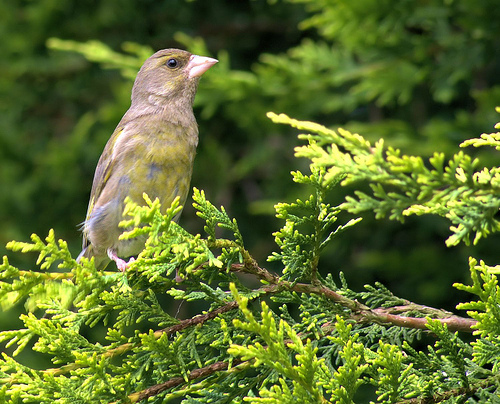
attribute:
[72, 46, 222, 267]
bird — brown, small, sideways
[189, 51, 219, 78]
beak — sharp, white, beige, pink, pointy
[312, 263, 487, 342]
branch — brown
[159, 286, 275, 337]
branch — weak, thin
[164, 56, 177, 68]
eye — round, black, beady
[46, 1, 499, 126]
leaves — green, blurry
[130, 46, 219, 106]
head — light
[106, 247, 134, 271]
foot — small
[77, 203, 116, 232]
feather — blue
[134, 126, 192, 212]
stomach — yellow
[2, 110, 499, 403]
leaves — lite